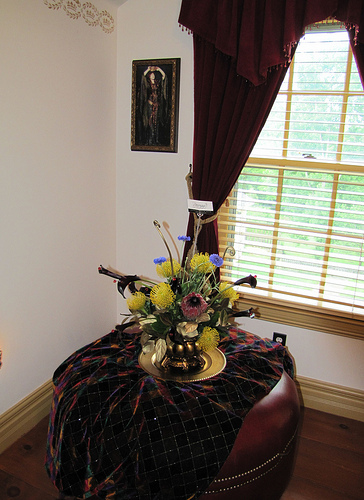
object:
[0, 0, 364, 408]
wall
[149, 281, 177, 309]
flower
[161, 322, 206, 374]
vase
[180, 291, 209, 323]
flower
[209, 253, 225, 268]
flower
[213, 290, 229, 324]
greenery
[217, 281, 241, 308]
flowers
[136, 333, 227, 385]
plate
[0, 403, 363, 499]
floors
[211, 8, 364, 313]
blinds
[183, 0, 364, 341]
window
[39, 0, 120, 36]
design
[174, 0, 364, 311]
curtains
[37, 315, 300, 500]
blanket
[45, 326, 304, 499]
cushion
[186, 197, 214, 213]
card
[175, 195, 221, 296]
stand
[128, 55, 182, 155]
picture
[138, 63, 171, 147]
woman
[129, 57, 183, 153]
brown frame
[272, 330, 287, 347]
outlet